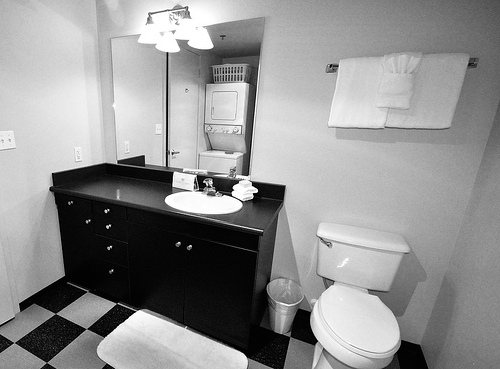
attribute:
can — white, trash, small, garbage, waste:
[261, 274, 304, 335]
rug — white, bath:
[99, 306, 249, 368]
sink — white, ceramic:
[166, 189, 243, 220]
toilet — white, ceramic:
[311, 218, 414, 366]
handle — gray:
[185, 244, 195, 256]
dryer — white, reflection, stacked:
[202, 85, 250, 139]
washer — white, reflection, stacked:
[198, 153, 247, 179]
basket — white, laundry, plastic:
[208, 58, 253, 83]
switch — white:
[0, 130, 17, 154]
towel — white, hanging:
[326, 58, 389, 137]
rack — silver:
[326, 53, 484, 73]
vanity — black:
[49, 159, 285, 351]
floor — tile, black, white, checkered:
[3, 276, 427, 367]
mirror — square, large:
[108, 14, 268, 178]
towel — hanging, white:
[385, 49, 469, 131]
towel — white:
[379, 49, 423, 111]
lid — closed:
[319, 283, 400, 355]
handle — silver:
[317, 231, 333, 249]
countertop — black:
[65, 173, 284, 232]